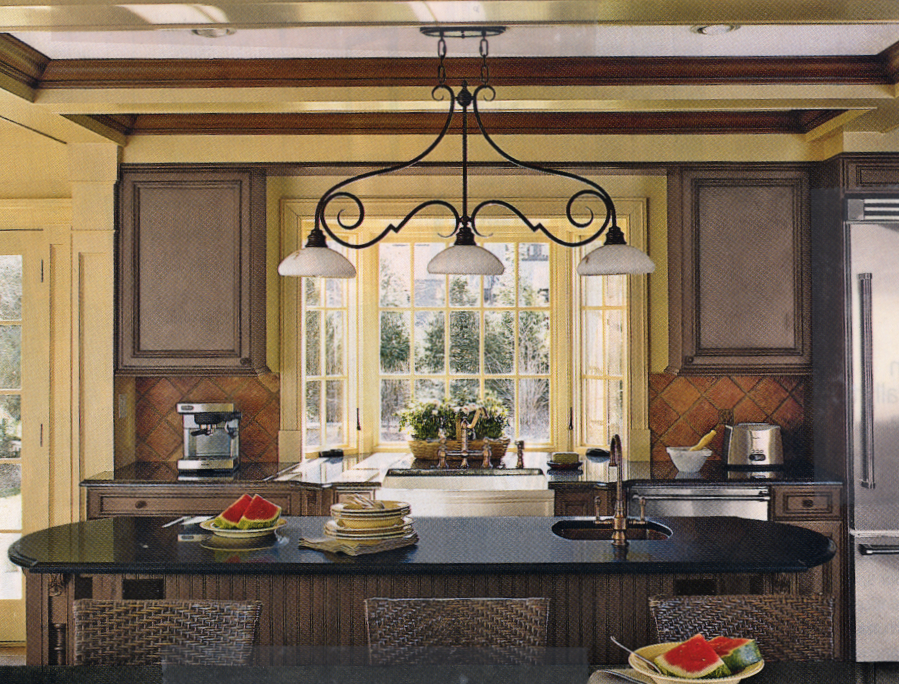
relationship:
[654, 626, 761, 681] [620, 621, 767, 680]
watermelon in bowl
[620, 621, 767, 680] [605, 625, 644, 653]
bowl with spoon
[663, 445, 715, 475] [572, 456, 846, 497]
bowl on counter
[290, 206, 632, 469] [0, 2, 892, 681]
window in kitchen